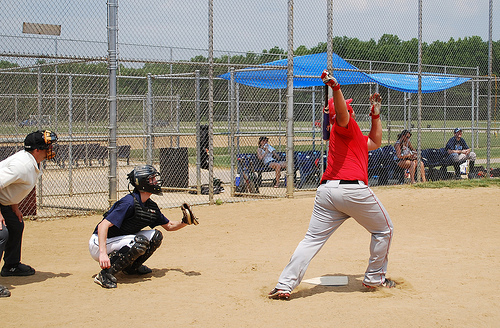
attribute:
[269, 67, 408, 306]
man — playing, batting, white, tall, focused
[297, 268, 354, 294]
plate — white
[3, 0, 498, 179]
fence — grey, high, closed, tall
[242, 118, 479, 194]
people — sitting, watching, white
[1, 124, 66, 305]
umpire — thick, big, large, squatting, white, looking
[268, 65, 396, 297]
body — twisted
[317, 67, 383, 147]
arms — raised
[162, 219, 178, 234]
elbow — bent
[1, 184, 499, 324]
ground — brown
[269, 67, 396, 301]
batter — baseball batter